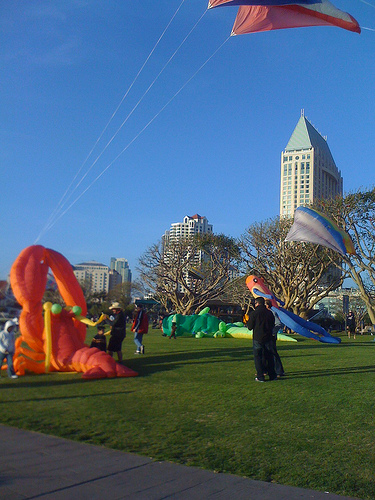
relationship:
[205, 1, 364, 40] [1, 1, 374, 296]
kite in sky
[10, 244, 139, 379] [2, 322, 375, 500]
balloon sitting on grass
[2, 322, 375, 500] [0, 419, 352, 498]
grass beside of sidewalk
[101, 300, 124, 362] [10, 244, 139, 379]
person close to balloon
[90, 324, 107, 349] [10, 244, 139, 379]
person close to balloon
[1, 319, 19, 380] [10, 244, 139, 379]
person close to balloon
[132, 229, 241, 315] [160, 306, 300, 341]
tree behind balloon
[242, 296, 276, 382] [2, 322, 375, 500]
man standing in grass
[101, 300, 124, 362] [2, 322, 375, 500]
person standing in grass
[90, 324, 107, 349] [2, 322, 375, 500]
person standing in grass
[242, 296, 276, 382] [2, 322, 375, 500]
man walking on grass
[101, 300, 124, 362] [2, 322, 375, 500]
person walking on grass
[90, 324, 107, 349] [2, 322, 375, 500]
person walking on grass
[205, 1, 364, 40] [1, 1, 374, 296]
kite flying sky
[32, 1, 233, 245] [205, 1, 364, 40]
strings are attached to kite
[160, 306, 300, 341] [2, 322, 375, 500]
balloon on grass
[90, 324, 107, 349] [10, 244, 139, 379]
person beside balloon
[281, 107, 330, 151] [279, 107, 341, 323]
tower on top of building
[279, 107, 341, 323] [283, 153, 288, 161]
building has a window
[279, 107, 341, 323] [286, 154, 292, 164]
building has a window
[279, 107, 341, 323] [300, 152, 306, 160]
building has a window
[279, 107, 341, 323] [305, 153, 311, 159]
building has a window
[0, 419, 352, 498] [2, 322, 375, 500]
sidewalk beside grass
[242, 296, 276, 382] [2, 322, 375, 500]
man standing on grass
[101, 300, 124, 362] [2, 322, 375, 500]
person standing on grass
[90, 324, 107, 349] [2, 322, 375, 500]
person standing on grass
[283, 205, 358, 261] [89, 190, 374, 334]
balloon in front of trees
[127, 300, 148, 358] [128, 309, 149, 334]
person wearing a coat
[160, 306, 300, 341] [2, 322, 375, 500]
balloon laning on grass